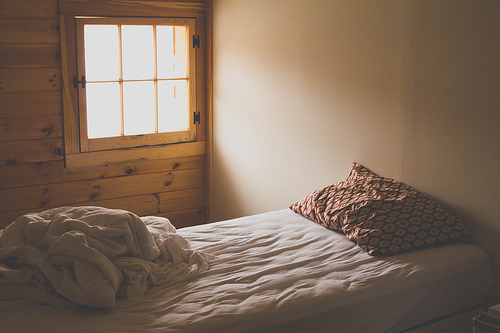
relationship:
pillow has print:
[291, 157, 473, 255] [378, 200, 432, 240]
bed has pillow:
[215, 253, 499, 332] [291, 157, 473, 255]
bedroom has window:
[1, 0, 498, 331] [77, 17, 198, 152]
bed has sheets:
[215, 253, 499, 332] [0, 204, 211, 313]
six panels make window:
[83, 25, 190, 138] [77, 17, 198, 152]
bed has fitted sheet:
[215, 253, 499, 332] [223, 208, 288, 313]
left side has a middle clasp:
[64, 15, 86, 169] [71, 73, 88, 92]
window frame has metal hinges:
[77, 17, 198, 152] [187, 33, 207, 52]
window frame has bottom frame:
[77, 17, 198, 152] [188, 110, 206, 130]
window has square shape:
[77, 17, 198, 152] [62, 3, 204, 162]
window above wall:
[77, 17, 198, 152] [13, 3, 85, 227]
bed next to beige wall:
[215, 253, 499, 332] [210, 5, 293, 216]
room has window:
[1, 0, 498, 331] [77, 17, 198, 152]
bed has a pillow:
[215, 253, 499, 332] [291, 157, 473, 255]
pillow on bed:
[291, 157, 473, 255] [215, 253, 499, 332]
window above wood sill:
[77, 17, 198, 152] [63, 135, 210, 170]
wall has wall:
[13, 3, 85, 227] [13, 3, 85, 227]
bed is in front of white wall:
[215, 253, 499, 332] [210, 5, 293, 216]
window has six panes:
[77, 17, 198, 152] [83, 25, 190, 138]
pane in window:
[118, 82, 158, 128] [77, 17, 198, 152]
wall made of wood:
[13, 12, 103, 234] [17, 168, 96, 192]